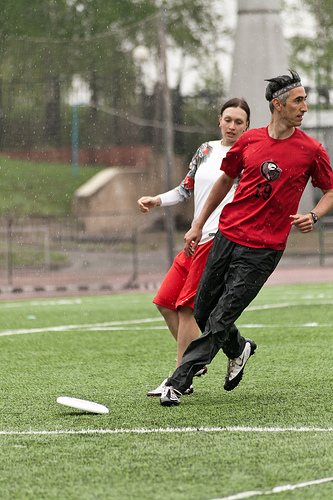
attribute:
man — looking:
[161, 69, 331, 404]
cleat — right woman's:
[146, 375, 198, 394]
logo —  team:
[250, 151, 281, 215]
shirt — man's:
[207, 113, 321, 249]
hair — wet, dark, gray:
[261, 74, 304, 99]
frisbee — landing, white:
[57, 390, 113, 424]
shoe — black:
[160, 341, 252, 413]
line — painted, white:
[9, 303, 327, 498]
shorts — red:
[152, 237, 209, 317]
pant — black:
[165, 233, 283, 413]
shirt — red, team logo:
[217, 131, 333, 249]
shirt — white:
[187, 137, 234, 235]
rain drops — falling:
[4, 9, 325, 296]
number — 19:
[249, 184, 279, 201]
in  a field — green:
[9, 270, 331, 496]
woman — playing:
[137, 90, 250, 395]